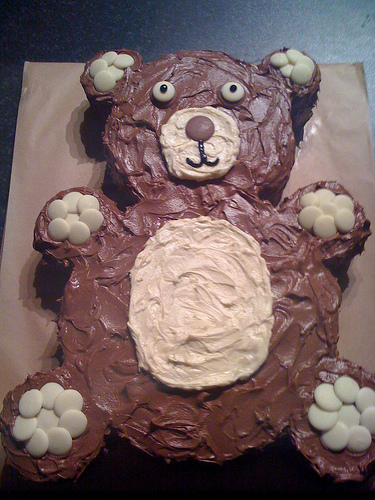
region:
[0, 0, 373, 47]
table with black surface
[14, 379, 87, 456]
white circular chips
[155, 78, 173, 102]
white circular chip with black bead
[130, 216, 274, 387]
center of bear tummy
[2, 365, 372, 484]
both of bear's feet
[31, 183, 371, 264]
both of bear's front feet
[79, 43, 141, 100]
bear ear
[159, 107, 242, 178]
bear snout, nose and mouth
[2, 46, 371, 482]
edible bear cake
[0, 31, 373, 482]
this is a cake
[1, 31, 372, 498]
a chocolate cake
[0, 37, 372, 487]
the cake is shaped like a bear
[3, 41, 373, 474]
the cake is decorated to look like a bear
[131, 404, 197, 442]
this frosting is chocolate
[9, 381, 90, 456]
white chocolate candy circles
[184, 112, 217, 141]
the nose is chocolate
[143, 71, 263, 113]
these are the eyes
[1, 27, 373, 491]
there is frosting on the cake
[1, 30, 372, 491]
the entire cake is covered in chocolate frosting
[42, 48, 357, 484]
a teddy bear cake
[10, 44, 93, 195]
brown paper that the cake is sitting on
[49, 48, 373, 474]
a chocolate teddy bear cake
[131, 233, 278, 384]
light chocolate on the teddy bear cake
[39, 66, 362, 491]
a homemade cake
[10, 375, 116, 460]
white candy in the paw of the cake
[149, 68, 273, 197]
the face of the teddy bear cake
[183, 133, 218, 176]
black icing to make the lines from the nose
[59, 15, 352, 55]
black counter top the cake is sitting on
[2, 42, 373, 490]
A chocolated frosted bear cake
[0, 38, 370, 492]
A chocolated frosted bear cake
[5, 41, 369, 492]
A chocolated frosted bear cake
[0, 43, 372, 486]
A chocolated frosted bear cake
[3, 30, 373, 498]
a chocolate cake in the shape of a bear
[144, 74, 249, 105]
white eyes of the bear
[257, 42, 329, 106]
right ear of bear has white candies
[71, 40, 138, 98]
left ear of bear has white candies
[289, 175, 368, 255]
right arm of bear has white candies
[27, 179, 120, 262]
left ear of bear has white candies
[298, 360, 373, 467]
right leg of bear has white candies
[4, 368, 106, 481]
left ear of bear has white candies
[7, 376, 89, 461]
candies forming a circle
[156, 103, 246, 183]
the snout of bear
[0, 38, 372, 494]
A homemade teddy bear cake.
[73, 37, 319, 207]
A brown teddy bear cake face.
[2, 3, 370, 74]
A black slate counter.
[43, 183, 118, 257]
White chocolate pieces on the left paw.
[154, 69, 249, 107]
Two teddy bear candy eyes.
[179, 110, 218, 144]
A brown chocolate piece for the teddy bears nose.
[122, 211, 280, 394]
A patch of tan icing for the teddy bears tummy.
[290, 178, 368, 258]
White chocolate pieces for the right paw.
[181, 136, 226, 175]
A thin line of black frosting for the teddy bears mouth.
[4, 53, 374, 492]
A tan cake board with a cake teddy bear on it.